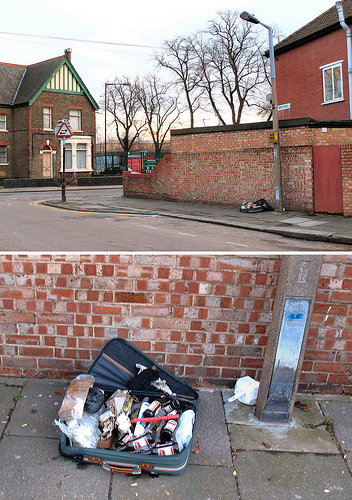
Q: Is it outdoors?
A: Yes, it is outdoors.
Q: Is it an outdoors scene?
A: Yes, it is outdoors.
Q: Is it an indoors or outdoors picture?
A: It is outdoors.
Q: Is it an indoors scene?
A: No, it is outdoors.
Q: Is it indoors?
A: No, it is outdoors.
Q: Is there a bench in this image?
A: No, there are no benches.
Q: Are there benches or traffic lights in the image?
A: No, there are no benches or traffic lights.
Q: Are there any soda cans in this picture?
A: No, there are no soda cans.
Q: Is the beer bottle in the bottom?
A: Yes, the beer bottle is in the bottom of the image.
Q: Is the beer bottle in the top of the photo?
A: No, the beer bottle is in the bottom of the image.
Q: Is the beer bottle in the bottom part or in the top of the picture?
A: The beer bottle is in the bottom of the image.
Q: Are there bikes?
A: No, there are no bikes.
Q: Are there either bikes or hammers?
A: No, there are no bikes or hammers.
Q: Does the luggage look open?
A: Yes, the luggage is open.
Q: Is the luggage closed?
A: No, the luggage is open.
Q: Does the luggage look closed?
A: No, the luggage is open.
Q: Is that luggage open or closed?
A: The luggage is open.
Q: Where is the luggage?
A: The luggage is on the ground.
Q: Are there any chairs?
A: No, there are no chairs.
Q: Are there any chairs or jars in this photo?
A: No, there are no chairs or jars.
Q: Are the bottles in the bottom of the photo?
A: Yes, the bottles are in the bottom of the image.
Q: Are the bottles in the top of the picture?
A: No, the bottles are in the bottom of the image.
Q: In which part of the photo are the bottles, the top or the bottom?
A: The bottles are in the bottom of the image.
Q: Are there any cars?
A: No, there are no cars.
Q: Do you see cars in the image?
A: No, there are no cars.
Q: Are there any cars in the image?
A: No, there are no cars.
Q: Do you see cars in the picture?
A: No, there are no cars.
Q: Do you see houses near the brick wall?
A: Yes, there is a house near the wall.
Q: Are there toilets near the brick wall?
A: No, there is a house near the wall.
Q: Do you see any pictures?
A: No, there are no pictures.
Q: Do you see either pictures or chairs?
A: No, there are no pictures or chairs.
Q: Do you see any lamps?
A: Yes, there is a lamp.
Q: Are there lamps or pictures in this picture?
A: Yes, there is a lamp.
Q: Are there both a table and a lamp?
A: No, there is a lamp but no tables.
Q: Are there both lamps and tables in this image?
A: No, there is a lamp but no tables.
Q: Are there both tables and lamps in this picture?
A: No, there is a lamp but no tables.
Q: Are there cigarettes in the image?
A: No, there are no cigarettes.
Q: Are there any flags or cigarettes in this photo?
A: No, there are no cigarettes or flags.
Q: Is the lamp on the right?
A: Yes, the lamp is on the right of the image.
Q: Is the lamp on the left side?
A: No, the lamp is on the right of the image.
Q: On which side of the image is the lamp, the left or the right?
A: The lamp is on the right of the image.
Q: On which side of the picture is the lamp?
A: The lamp is on the right of the image.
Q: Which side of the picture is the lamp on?
A: The lamp is on the right of the image.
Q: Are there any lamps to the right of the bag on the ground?
A: Yes, there is a lamp to the right of the bag.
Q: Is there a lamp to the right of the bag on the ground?
A: Yes, there is a lamp to the right of the bag.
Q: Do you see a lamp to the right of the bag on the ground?
A: Yes, there is a lamp to the right of the bag.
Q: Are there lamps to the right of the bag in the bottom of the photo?
A: Yes, there is a lamp to the right of the bag.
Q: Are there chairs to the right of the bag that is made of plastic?
A: No, there is a lamp to the right of the bag.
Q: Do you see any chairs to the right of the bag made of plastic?
A: No, there is a lamp to the right of the bag.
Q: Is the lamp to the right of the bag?
A: Yes, the lamp is to the right of the bag.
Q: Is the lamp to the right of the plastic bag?
A: Yes, the lamp is to the right of the bag.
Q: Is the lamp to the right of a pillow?
A: No, the lamp is to the right of the bag.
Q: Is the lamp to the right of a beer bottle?
A: Yes, the lamp is to the right of a beer bottle.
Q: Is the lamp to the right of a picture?
A: No, the lamp is to the right of a beer bottle.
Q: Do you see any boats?
A: No, there are no boats.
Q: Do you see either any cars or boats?
A: No, there are no boats or cars.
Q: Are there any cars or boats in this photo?
A: No, there are no boats or cars.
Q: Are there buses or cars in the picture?
A: No, there are no cars or buses.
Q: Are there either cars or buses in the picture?
A: No, there are no cars or buses.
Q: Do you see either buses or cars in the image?
A: No, there are no cars or buses.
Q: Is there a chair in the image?
A: No, there are no chairs.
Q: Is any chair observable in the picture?
A: No, there are no chairs.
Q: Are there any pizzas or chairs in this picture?
A: No, there are no chairs or pizzas.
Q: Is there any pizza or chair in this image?
A: No, there are no chairs or pizzas.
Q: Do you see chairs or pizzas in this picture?
A: No, there are no chairs or pizzas.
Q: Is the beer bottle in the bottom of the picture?
A: Yes, the beer bottle is in the bottom of the image.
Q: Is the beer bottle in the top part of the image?
A: No, the beer bottle is in the bottom of the image.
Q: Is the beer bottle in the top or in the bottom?
A: The beer bottle is in the bottom of the image.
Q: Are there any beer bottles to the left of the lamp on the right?
A: Yes, there is a beer bottle to the left of the lamp.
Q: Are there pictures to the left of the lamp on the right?
A: No, there is a beer bottle to the left of the lamp.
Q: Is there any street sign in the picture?
A: Yes, there is a street sign.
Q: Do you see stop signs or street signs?
A: Yes, there is a street sign.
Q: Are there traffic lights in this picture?
A: No, there are no traffic lights.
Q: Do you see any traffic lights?
A: No, there are no traffic lights.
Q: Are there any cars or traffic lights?
A: No, there are no traffic lights or cars.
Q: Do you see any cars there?
A: No, there are no cars.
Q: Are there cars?
A: No, there are no cars.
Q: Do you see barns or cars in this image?
A: No, there are no cars or barns.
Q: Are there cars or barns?
A: No, there are no cars or barns.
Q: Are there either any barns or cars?
A: No, there are no cars or barns.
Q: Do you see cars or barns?
A: No, there are no cars or barns.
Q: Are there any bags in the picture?
A: Yes, there is a bag.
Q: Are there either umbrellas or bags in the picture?
A: Yes, there is a bag.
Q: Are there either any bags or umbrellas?
A: Yes, there is a bag.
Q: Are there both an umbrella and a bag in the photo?
A: No, there is a bag but no umbrellas.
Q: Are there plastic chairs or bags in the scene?
A: Yes, there is a plastic bag.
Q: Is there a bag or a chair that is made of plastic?
A: Yes, the bag is made of plastic.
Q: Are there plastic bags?
A: Yes, there is a bag that is made of plastic.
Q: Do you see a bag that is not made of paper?
A: Yes, there is a bag that is made of plastic.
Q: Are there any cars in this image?
A: No, there are no cars.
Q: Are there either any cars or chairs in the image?
A: No, there are no cars or chairs.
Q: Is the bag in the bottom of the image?
A: Yes, the bag is in the bottom of the image.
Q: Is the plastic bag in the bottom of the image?
A: Yes, the bag is in the bottom of the image.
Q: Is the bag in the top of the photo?
A: No, the bag is in the bottom of the image.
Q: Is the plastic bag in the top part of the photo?
A: No, the bag is in the bottom of the image.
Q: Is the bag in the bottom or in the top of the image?
A: The bag is in the bottom of the image.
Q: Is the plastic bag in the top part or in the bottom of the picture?
A: The bag is in the bottom of the image.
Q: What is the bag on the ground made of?
A: The bag is made of plastic.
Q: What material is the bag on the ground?
A: The bag is made of plastic.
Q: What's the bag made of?
A: The bag is made of plastic.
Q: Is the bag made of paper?
A: No, the bag is made of plastic.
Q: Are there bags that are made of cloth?
A: No, there is a bag but it is made of plastic.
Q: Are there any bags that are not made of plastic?
A: No, there is a bag but it is made of plastic.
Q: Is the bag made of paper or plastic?
A: The bag is made of plastic.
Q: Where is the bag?
A: The bag is on the ground.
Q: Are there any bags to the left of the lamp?
A: Yes, there is a bag to the left of the lamp.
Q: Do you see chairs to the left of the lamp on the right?
A: No, there is a bag to the left of the lamp.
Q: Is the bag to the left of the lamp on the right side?
A: Yes, the bag is to the left of the lamp.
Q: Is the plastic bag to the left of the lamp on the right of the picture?
A: Yes, the bag is to the left of the lamp.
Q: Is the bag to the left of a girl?
A: No, the bag is to the left of the lamp.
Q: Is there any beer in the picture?
A: Yes, there is beer.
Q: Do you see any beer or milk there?
A: Yes, there is beer.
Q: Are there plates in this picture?
A: No, there are no plates.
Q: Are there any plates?
A: No, there are no plates.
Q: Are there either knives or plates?
A: No, there are no plates or knives.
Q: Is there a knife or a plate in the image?
A: No, there are no plates or knives.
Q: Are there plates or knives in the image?
A: No, there are no plates or knives.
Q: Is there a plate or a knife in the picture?
A: No, there are no plates or knives.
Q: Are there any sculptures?
A: No, there are no sculptures.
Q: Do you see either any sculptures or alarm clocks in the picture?
A: No, there are no sculptures or alarm clocks.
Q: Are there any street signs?
A: Yes, there is a street sign.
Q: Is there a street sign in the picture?
A: Yes, there is a street sign.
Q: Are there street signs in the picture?
A: Yes, there is a street sign.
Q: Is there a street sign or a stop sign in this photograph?
A: Yes, there is a street sign.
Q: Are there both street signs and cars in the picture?
A: No, there is a street sign but no cars.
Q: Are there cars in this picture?
A: No, there are no cars.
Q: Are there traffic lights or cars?
A: No, there are no cars or traffic lights.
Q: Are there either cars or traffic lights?
A: No, there are no cars or traffic lights.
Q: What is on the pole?
A: The street sign is on the pole.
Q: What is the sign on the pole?
A: The sign is a street sign.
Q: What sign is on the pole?
A: The sign is a street sign.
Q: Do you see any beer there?
A: Yes, there is beer.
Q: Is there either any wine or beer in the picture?
A: Yes, there is beer.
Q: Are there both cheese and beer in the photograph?
A: No, there is beer but no cheese.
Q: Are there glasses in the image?
A: No, there are no glasses.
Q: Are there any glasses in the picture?
A: No, there are no glasses.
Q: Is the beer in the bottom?
A: Yes, the beer is in the bottom of the image.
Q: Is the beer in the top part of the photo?
A: No, the beer is in the bottom of the image.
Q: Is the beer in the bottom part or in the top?
A: The beer is in the bottom of the image.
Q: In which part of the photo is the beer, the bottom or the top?
A: The beer is in the bottom of the image.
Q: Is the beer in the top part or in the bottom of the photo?
A: The beer is in the bottom of the image.